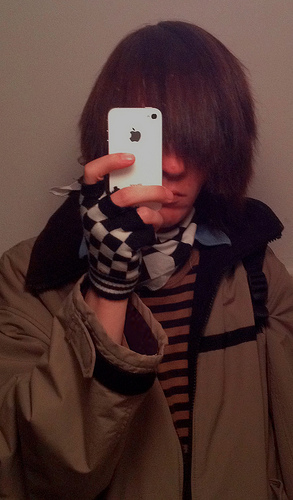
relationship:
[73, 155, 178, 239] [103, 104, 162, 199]
hand holding apple phone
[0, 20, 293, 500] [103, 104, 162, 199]
man holding apple phone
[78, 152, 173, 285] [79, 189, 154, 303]
hand wearing glove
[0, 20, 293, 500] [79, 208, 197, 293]
man wearing bandanna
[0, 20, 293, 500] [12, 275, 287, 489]
man wearing jacket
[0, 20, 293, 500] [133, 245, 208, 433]
man wearing shirt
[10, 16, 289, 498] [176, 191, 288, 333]
man has shoulder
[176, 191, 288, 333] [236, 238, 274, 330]
shoulder has strap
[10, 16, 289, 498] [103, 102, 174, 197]
man holds iphone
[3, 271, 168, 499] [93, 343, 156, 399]
jacket sleeve has velcro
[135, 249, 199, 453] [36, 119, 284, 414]
stripe on persons shirt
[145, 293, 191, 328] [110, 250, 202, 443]
stripe on persons shirt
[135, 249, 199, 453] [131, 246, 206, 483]
stripe on shirt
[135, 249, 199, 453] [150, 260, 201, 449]
stripe on shirt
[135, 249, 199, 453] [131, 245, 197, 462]
stripe on shirt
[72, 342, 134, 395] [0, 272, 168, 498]
velco strap on jacket sleeve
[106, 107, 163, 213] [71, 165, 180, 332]
apple phone in a hand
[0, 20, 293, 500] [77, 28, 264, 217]
man with hair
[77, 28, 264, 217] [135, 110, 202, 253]
hair covering h face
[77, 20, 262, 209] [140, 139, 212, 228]
hair covers face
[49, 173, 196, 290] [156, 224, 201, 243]
bandanna covers neck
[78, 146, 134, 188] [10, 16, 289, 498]
finger on man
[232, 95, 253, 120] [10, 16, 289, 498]
ground on man